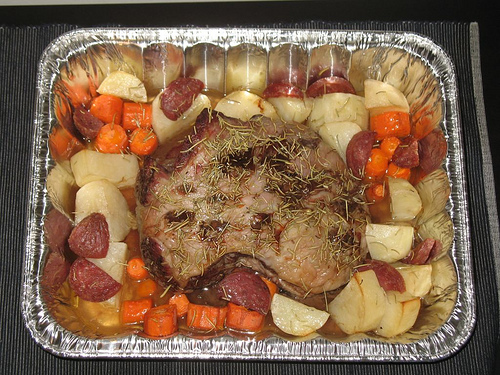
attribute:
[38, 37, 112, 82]
pan — aluminum, rounded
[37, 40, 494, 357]
pan — aluminum 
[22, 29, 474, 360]
pan — aluminum , shiny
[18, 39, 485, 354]
foil pan — aluminum 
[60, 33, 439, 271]
container — aluminum 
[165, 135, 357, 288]
beef — roasted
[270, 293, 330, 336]
potato — white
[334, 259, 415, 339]
potato — white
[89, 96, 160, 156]
carrots — cut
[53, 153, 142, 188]
sliced potato — white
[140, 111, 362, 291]
meat — cooked